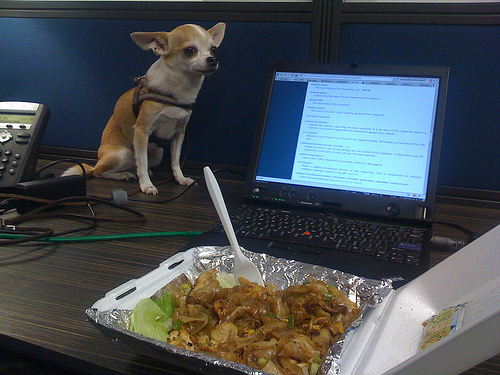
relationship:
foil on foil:
[80, 245, 403, 372] [123, 269, 361, 375]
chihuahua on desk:
[57, 21, 227, 197] [1, 156, 498, 373]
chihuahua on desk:
[57, 21, 227, 197] [41, 220, 202, 325]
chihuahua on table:
[57, 21, 227, 197] [0, 156, 499, 373]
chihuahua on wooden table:
[57, 21, 227, 197] [8, 245, 113, 330]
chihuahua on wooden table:
[57, 21, 227, 197] [1, 150, 498, 374]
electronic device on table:
[0, 97, 49, 217] [32, 231, 74, 311]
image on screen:
[296, 77, 435, 189] [259, 73, 431, 195]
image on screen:
[296, 77, 435, 189] [262, 75, 429, 186]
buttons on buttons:
[231, 203, 423, 260] [209, 203, 427, 267]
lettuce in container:
[105, 287, 215, 355] [93, 191, 497, 371]